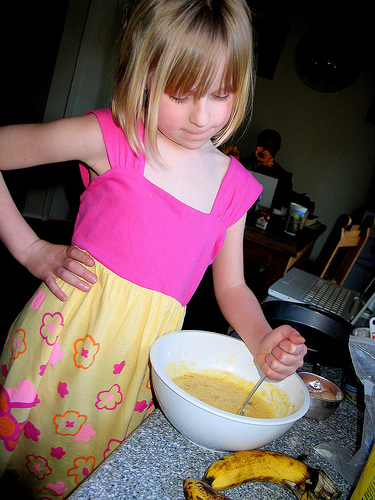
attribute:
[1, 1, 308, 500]
girl — little, mixing, stirring, looking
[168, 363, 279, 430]
food — yellow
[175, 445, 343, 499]
food — yellow, over ripe, brown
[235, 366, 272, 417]
utensil — metal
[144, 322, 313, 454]
bowl — white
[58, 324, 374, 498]
counter — gray, granite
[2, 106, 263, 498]
dress — yellow, flower print, pink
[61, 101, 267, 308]
top — pink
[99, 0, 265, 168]
hair — blonde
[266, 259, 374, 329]
laptop — open, gray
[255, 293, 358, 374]
pan — nonstick, circular, cake, black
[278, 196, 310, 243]
cup — plastic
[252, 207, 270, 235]
cigarettes — marlboro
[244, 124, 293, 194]
person — sitting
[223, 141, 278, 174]
flowers — orange